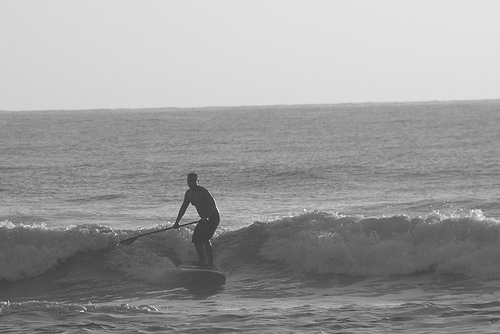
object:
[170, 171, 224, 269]
man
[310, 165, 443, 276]
water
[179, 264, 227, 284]
surboard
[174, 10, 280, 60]
sky